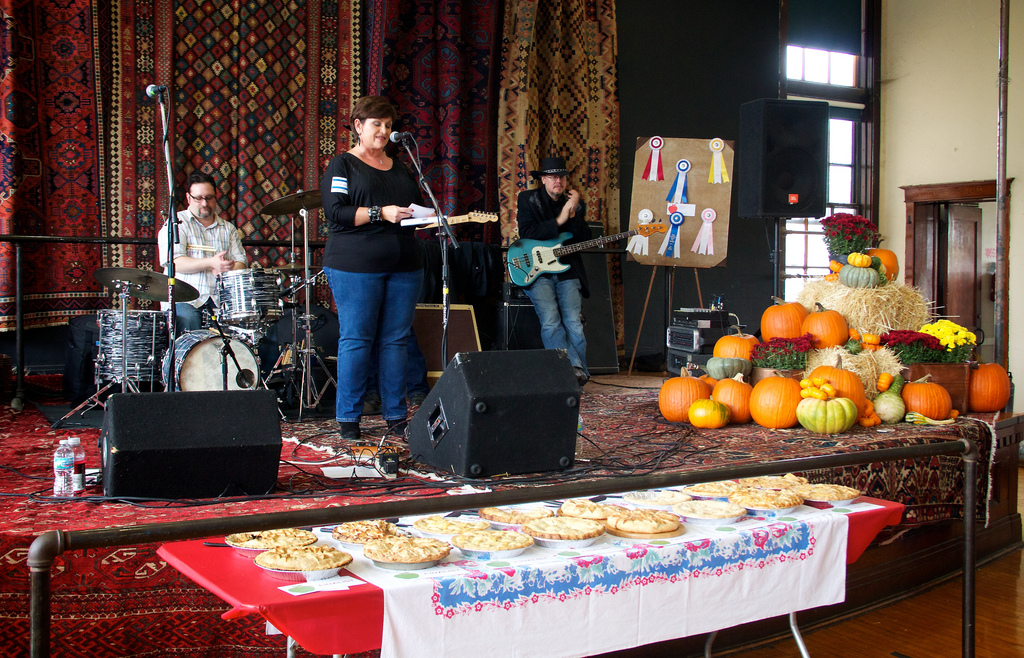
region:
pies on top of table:
[157, 473, 908, 655]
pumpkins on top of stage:
[656, 215, 1015, 435]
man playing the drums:
[66, 168, 342, 416]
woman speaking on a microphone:
[322, 94, 459, 452]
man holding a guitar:
[502, 157, 674, 386]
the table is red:
[155, 468, 908, 655]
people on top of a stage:
[6, 85, 1022, 611]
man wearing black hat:
[511, 151, 601, 383]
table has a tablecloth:
[157, 452, 901, 653]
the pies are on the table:
[356, 513, 592, 568]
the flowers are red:
[822, 208, 871, 250]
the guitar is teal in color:
[506, 228, 584, 285]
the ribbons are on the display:
[637, 121, 735, 283]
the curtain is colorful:
[201, 45, 278, 148]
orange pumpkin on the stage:
[656, 368, 707, 429]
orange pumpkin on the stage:
[706, 378, 752, 421]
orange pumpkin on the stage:
[746, 371, 803, 428]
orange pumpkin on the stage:
[899, 374, 951, 426]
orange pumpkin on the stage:
[962, 352, 1014, 413]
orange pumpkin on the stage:
[757, 292, 796, 335]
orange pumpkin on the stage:
[710, 318, 750, 358]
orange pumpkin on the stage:
[855, 394, 876, 423]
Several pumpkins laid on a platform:
[673, 377, 775, 417]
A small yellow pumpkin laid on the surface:
[694, 402, 718, 425]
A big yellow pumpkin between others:
[757, 384, 793, 424]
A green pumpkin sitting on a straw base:
[843, 268, 869, 284]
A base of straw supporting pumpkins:
[844, 287, 898, 307]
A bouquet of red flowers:
[828, 216, 861, 246]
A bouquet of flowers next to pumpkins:
[828, 217, 861, 249]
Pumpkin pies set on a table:
[468, 519, 579, 539]